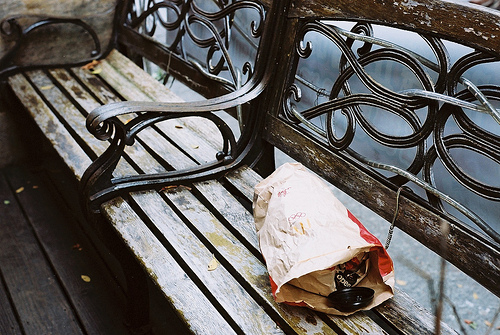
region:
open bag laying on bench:
[231, 160, 395, 325]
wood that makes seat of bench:
[130, 196, 257, 308]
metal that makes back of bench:
[310, 29, 470, 134]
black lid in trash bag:
[322, 282, 396, 312]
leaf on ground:
[60, 267, 110, 289]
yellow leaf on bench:
[203, 250, 223, 290]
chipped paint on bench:
[367, 0, 489, 40]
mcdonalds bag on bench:
[272, 200, 335, 259]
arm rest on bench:
[76, 97, 269, 164]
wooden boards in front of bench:
[22, 200, 108, 334]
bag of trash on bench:
[257, 169, 356, 294]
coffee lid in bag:
[331, 279, 389, 321]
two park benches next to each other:
[60, 68, 298, 333]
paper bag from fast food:
[252, 161, 366, 297]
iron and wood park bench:
[236, 18, 472, 313]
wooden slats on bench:
[139, 209, 236, 327]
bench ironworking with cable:
[331, 26, 481, 199]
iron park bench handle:
[92, 104, 206, 182]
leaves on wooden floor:
[11, 217, 89, 302]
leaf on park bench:
[61, 60, 126, 113]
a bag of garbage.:
[233, 158, 410, 313]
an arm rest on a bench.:
[75, 73, 265, 212]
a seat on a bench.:
[99, 164, 461, 333]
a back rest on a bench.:
[268, 0, 496, 300]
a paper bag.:
[235, 158, 407, 333]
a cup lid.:
[310, 278, 377, 324]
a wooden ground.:
[0, 194, 186, 332]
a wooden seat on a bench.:
[6, 34, 239, 190]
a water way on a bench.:
[283, 41, 495, 246]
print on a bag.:
[258, 183, 302, 203]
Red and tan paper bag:
[239, 154, 415, 326]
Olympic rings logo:
[282, 204, 313, 220]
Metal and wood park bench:
[8, 4, 496, 334]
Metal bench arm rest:
[50, 76, 306, 237]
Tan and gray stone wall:
[4, 0, 121, 99]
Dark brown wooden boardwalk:
[0, 90, 188, 333]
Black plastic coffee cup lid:
[322, 279, 378, 326]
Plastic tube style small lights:
[136, 3, 497, 220]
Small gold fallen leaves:
[36, 205, 247, 328]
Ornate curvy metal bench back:
[282, 8, 499, 190]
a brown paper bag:
[252, 162, 393, 317]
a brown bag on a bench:
[252, 161, 396, 315]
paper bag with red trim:
[252, 164, 396, 315]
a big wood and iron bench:
[1, 1, 498, 334]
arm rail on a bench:
[77, 98, 277, 220]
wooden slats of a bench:
[3, 48, 463, 334]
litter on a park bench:
[254, 158, 395, 313]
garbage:
[249, 162, 399, 318]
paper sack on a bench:
[250, 158, 399, 318]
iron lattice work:
[281, 9, 498, 251]